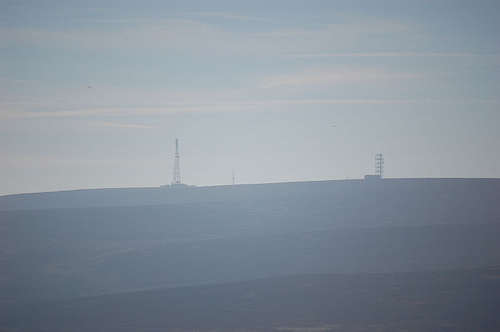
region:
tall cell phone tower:
[164, 133, 191, 185]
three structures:
[163, 124, 399, 184]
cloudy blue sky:
[3, 0, 494, 175]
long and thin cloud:
[25, 88, 399, 129]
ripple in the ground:
[77, 259, 488, 294]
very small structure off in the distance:
[228, 167, 238, 187]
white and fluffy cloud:
[265, 66, 405, 93]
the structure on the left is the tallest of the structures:
[160, 128, 402, 187]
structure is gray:
[371, 151, 389, 178]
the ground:
[3, 183, 498, 329]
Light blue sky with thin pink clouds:
[215, 12, 396, 114]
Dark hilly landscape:
[130, 203, 472, 323]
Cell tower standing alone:
[67, 128, 212, 205]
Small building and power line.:
[348, 143, 420, 191]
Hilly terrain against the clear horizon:
[25, 162, 127, 243]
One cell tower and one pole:
[145, 108, 433, 210]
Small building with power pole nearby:
[333, 98, 458, 210]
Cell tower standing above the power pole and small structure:
[140, 112, 414, 191]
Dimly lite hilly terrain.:
[122, 200, 384, 310]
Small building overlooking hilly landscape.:
[335, 149, 420, 304]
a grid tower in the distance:
[369, 145, 387, 180]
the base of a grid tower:
[364, 172, 381, 179]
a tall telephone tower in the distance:
[173, 136, 182, 195]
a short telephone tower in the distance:
[228, 169, 237, 184]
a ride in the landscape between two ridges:
[129, 226, 460, 248]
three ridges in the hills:
[68, 200, 483, 314]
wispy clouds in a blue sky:
[36, 92, 160, 144]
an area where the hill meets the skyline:
[23, 179, 162, 200]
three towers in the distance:
[154, 130, 396, 193]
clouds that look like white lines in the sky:
[286, 30, 498, 126]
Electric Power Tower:
[153, 127, 208, 192]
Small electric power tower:
[356, 145, 386, 187]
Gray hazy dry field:
[0, 194, 498, 328]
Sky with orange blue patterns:
[3, 0, 480, 125]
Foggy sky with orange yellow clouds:
[2, 0, 497, 165]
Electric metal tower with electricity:
[154, 131, 201, 201]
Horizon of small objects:
[104, 118, 461, 187]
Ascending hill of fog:
[5, 198, 481, 313]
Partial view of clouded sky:
[13, 0, 493, 130]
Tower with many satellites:
[363, 151, 396, 180]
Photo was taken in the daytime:
[1, 0, 497, 321]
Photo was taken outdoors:
[5, 7, 495, 325]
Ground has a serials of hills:
[5, 174, 494, 326]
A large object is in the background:
[151, 132, 199, 196]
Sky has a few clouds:
[1, 6, 496, 163]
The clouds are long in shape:
[23, 43, 473, 140]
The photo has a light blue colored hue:
[8, 6, 494, 328]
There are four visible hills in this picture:
[19, 173, 481, 330]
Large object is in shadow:
[151, 130, 202, 195]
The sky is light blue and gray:
[5, 6, 497, 79]